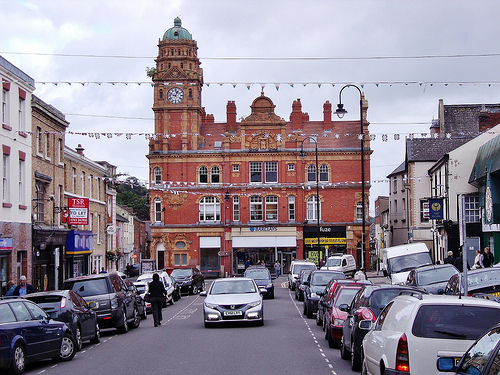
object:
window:
[264, 160, 279, 185]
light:
[396, 333, 411, 374]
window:
[196, 163, 208, 183]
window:
[211, 165, 221, 185]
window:
[198, 195, 222, 222]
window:
[248, 161, 263, 183]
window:
[307, 164, 317, 183]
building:
[146, 15, 374, 277]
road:
[86, 279, 335, 375]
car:
[359, 289, 500, 375]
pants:
[152, 296, 163, 325]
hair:
[153, 273, 160, 282]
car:
[200, 277, 268, 327]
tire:
[57, 332, 79, 363]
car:
[1, 296, 79, 374]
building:
[31, 92, 70, 292]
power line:
[0, 51, 500, 60]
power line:
[1, 80, 499, 85]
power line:
[2, 130, 499, 137]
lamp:
[333, 103, 348, 118]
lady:
[144, 273, 168, 327]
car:
[339, 283, 429, 372]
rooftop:
[406, 136, 477, 161]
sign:
[430, 200, 442, 219]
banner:
[67, 197, 88, 225]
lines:
[301, 314, 337, 374]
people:
[12, 275, 35, 296]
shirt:
[149, 280, 168, 298]